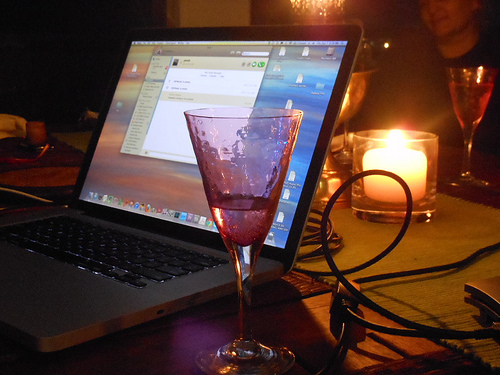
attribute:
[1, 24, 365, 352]
laptop — silver, on, gray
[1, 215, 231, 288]
keyboard — black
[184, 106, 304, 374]
glass — pink, purple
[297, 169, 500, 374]
cord — black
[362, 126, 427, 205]
candle — lit, white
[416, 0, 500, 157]
person — sitting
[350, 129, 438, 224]
glass — clear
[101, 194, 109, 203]
icon — white, small